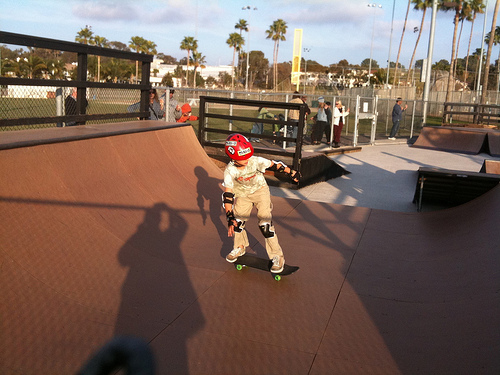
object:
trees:
[264, 21, 290, 84]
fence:
[0, 31, 154, 131]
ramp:
[0, 122, 224, 327]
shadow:
[114, 201, 208, 375]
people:
[283, 88, 306, 145]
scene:
[0, 0, 500, 375]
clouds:
[76, 1, 302, 28]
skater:
[219, 134, 302, 274]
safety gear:
[221, 161, 295, 238]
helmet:
[222, 133, 249, 162]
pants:
[225, 190, 284, 260]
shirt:
[221, 157, 282, 193]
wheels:
[232, 263, 279, 282]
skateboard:
[234, 252, 303, 282]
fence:
[192, 88, 309, 167]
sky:
[0, 0, 500, 70]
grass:
[182, 107, 318, 131]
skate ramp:
[442, 102, 498, 128]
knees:
[230, 217, 246, 236]